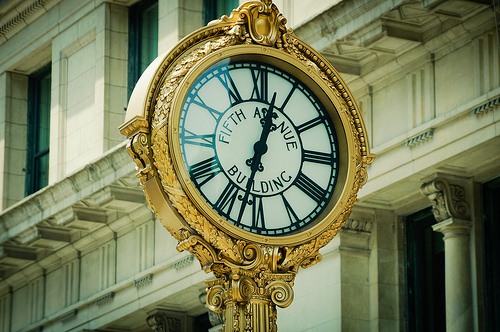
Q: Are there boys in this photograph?
A: No, there are no boys.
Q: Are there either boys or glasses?
A: No, there are no boys or glasses.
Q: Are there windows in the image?
A: Yes, there is a window.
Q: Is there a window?
A: Yes, there is a window.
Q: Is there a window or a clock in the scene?
A: Yes, there is a window.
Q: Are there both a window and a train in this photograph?
A: No, there is a window but no trains.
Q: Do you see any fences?
A: No, there are no fences.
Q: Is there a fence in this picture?
A: No, there are no fences.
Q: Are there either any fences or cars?
A: No, there are no fences or cars.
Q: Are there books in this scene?
A: No, there are no books.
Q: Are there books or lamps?
A: No, there are no books or lamps.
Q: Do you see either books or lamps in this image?
A: No, there are no books or lamps.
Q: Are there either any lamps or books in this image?
A: No, there are no books or lamps.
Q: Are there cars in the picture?
A: No, there are no cars.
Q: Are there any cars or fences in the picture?
A: No, there are no cars or fences.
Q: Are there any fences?
A: No, there are no fences.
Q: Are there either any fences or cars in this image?
A: No, there are no fences or cars.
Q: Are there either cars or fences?
A: No, there are no fences or cars.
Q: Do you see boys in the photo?
A: No, there are no boys.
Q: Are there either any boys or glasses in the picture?
A: No, there are no boys or glasses.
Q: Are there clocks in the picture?
A: Yes, there is a clock.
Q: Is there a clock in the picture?
A: Yes, there is a clock.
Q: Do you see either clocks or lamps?
A: Yes, there is a clock.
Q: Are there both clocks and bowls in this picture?
A: No, there is a clock but no bowls.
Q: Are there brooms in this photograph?
A: No, there are no brooms.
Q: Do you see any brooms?
A: No, there are no brooms.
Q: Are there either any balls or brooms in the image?
A: No, there are no brooms or balls.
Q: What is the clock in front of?
A: The clock is in front of the building.